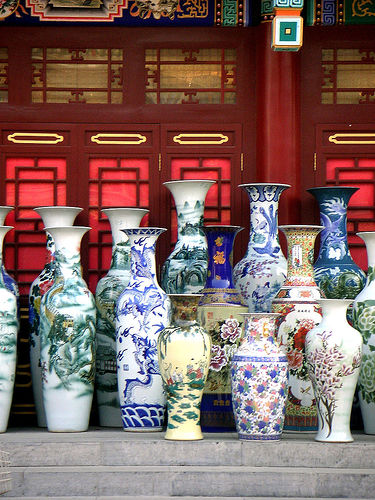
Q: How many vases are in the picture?
A: 15.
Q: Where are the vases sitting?
A: Stone step.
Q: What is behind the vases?
A: Screen with shutters.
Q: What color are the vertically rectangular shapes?
A: Red.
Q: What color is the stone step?
A: Grey.